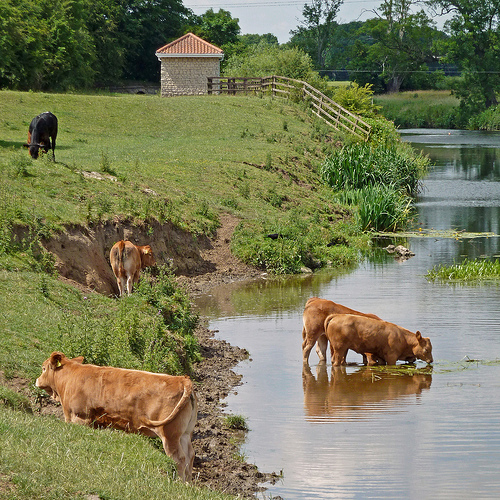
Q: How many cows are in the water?
A: Two.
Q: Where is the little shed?
A: In the back.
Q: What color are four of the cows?
A: Brown.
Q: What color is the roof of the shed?
A: Red.